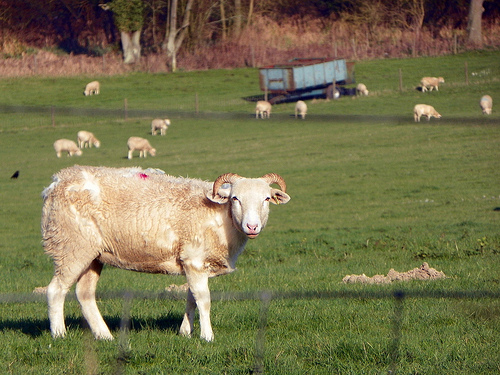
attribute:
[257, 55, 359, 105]
trailer — blue, rectangle, rusty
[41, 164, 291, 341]
ram — walking, dirty, furry, white, adult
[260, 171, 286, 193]
horn — curled, yellow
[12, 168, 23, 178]
bird — black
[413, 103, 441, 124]
sheep — grazing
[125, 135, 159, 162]
sheep — grazing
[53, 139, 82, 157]
sheep — grazing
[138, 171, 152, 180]
marking — purple, red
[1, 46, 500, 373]
grass — green, lush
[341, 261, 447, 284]
matter — tan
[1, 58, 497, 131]
fence — net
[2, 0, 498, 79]
foilage — brown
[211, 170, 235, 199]
horn — yellow